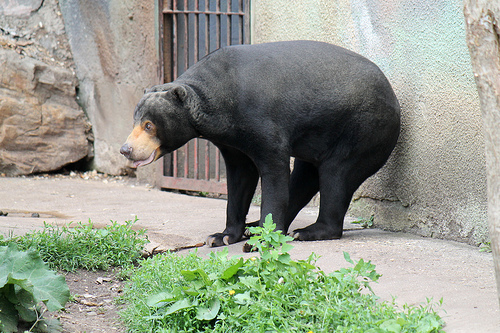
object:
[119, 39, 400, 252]
bear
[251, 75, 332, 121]
body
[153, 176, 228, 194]
bottom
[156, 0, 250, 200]
door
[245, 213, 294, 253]
leaves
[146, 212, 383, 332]
bush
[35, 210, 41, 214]
edge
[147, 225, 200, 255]
rock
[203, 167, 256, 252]
leg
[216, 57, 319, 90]
back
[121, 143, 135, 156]
snout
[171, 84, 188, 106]
ear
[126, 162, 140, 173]
tongue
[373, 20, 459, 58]
wall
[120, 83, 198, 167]
head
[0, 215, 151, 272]
grass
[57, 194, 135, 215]
sidewalk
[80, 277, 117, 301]
patch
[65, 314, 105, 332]
dirt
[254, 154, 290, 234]
left leg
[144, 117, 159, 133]
left eye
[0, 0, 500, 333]
zoo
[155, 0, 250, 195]
bars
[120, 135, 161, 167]
muzzle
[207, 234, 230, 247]
claws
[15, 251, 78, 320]
weeds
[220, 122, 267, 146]
fur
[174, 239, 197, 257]
crack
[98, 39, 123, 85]
red swirl